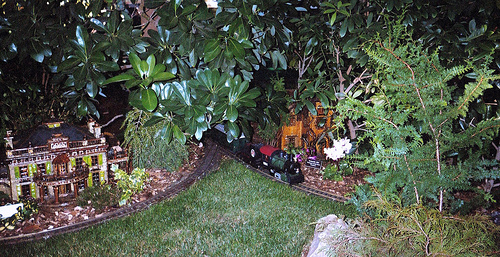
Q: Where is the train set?
A: On ground.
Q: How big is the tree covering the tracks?
A: Little.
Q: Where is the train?
A: On tracks.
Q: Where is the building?
A: Beside train tracks.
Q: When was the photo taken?
A: Daylight.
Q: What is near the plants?
A: A building.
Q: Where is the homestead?
A: Near the bushes.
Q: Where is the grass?
A: On the ground.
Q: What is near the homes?
A: Large plants.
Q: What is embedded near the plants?
A: Homesteads.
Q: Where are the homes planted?
A: On the ground.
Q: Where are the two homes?
A: On the ground.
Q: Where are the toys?
A: Under the tree.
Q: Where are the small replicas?
A: Near the bushes.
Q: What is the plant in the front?
A: Evergreen.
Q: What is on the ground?
A: Grass.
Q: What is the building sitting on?
A: Rocks.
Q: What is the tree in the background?
A: Magnolia.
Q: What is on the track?
A: Train.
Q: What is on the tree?
A: Leaves.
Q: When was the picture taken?
A: During the day.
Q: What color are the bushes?
A: Green.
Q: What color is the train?
A: Black.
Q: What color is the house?
A: Green.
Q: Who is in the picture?
A: No one.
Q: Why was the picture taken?
A: To capture the garden.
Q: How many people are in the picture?
A: None.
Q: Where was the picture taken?
A: In the air.